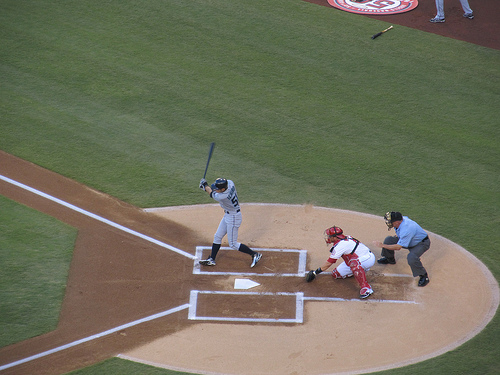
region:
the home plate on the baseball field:
[234, 277, 261, 289]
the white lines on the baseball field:
[0, 172, 420, 372]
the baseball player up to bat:
[197, 140, 263, 267]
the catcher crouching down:
[304, 225, 376, 298]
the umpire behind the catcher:
[377, 212, 430, 287]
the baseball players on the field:
[198, 142, 375, 298]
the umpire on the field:
[376, 210, 431, 286]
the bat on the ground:
[371, 24, 393, 38]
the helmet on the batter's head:
[210, 177, 229, 189]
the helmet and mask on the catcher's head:
[323, 226, 343, 245]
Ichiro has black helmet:
[202, 171, 236, 204]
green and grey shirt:
[207, 174, 232, 225]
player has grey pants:
[217, 200, 250, 271]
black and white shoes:
[240, 241, 263, 273]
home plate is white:
[227, 273, 264, 298]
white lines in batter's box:
[186, 230, 350, 296]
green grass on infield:
[2, 191, 64, 333]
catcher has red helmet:
[299, 229, 354, 250]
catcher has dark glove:
[305, 271, 326, 287]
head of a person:
[204, 171, 229, 194]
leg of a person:
[228, 218, 258, 258]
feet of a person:
[252, 253, 270, 266]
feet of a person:
[195, 255, 214, 265]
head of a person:
[315, 225, 343, 246]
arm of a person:
[309, 253, 341, 273]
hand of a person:
[300, 270, 317, 286]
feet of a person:
[357, 287, 374, 301]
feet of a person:
[410, 270, 433, 286]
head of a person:
[377, 210, 412, 227]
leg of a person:
[202, 200, 259, 272]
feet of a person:
[238, 248, 268, 268]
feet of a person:
[195, 255, 220, 273]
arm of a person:
[200, 183, 220, 200]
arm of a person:
[300, 252, 340, 284]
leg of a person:
[340, 258, 372, 289]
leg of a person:
[405, 242, 437, 282]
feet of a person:
[417, 275, 432, 293]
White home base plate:
[233, 276, 262, 294]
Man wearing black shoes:
[376, 210, 433, 288]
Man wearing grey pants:
[376, 210, 433, 287]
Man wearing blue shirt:
[376, 210, 433, 287]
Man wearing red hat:
[304, 225, 376, 300]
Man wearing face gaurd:
[301, 225, 378, 300]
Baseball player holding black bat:
[196, 138, 263, 267]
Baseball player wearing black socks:
[198, 175, 263, 269]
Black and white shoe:
[249, 250, 262, 267]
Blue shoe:
[416, 274, 430, 287]